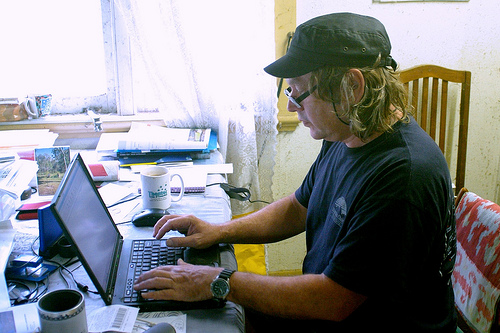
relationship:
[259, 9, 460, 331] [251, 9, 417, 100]
man wearing cap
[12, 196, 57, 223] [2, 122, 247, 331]
wallet sitting on desk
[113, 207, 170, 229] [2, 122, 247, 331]
corded mouse sitting on desk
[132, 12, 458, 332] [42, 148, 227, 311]
man working on laptop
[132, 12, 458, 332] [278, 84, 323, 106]
man wearing reading glasses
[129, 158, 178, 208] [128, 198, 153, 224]
mug near mouse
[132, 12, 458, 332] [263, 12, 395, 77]
man wearing cap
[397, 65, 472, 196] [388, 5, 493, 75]
chair close to wall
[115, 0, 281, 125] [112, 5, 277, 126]
screen near window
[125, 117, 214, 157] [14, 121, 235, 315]
books are on table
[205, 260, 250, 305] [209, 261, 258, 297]
wrist on watch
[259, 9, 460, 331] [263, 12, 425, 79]
man wearing cap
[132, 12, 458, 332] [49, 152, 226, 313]
man typing on laptop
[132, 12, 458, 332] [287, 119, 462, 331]
man wearing t-shirt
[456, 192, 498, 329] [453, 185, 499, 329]
blanket draped over chair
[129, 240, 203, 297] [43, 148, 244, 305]
keyboard of laptop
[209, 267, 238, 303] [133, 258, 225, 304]
watch on hand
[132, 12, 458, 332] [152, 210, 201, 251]
man typing with fingers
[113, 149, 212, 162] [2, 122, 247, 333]
files on desk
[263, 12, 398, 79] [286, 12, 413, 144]
cap on head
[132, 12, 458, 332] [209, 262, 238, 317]
man wearing watch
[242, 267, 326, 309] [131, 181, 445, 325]
hair on arm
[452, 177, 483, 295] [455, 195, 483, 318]
chair made of cloth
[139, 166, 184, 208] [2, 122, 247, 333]
mug on desk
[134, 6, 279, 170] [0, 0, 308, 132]
curtain by window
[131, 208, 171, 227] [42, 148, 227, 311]
corded mouse beside laptop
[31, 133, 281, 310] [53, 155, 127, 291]
laptop has screen